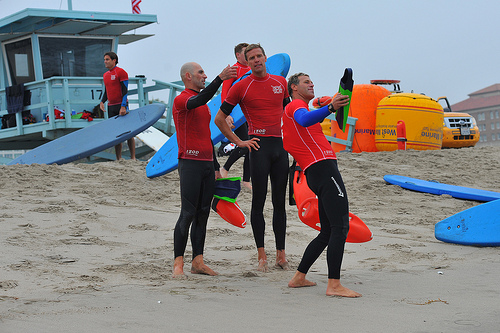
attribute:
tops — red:
[175, 112, 335, 153]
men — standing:
[153, 55, 353, 282]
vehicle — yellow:
[433, 98, 497, 158]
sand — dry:
[34, 174, 474, 311]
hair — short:
[289, 75, 300, 85]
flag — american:
[126, 2, 156, 13]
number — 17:
[89, 87, 106, 100]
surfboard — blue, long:
[388, 168, 491, 212]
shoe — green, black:
[213, 169, 244, 202]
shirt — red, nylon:
[98, 72, 131, 101]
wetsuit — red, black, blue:
[172, 90, 215, 233]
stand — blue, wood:
[1, 47, 168, 120]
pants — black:
[179, 163, 350, 250]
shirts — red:
[181, 95, 327, 145]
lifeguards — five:
[93, 48, 354, 194]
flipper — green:
[311, 71, 359, 125]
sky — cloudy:
[163, 6, 500, 71]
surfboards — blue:
[374, 173, 498, 239]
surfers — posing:
[160, 44, 347, 147]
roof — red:
[370, 81, 410, 92]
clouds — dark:
[342, 22, 469, 78]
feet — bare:
[171, 256, 222, 287]